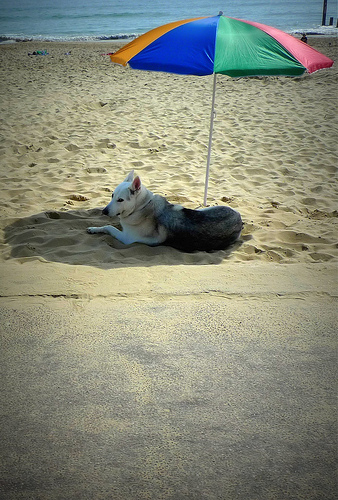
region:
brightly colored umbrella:
[103, 7, 333, 82]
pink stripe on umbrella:
[230, 13, 334, 67]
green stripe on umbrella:
[212, 12, 305, 75]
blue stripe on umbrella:
[124, 10, 217, 75]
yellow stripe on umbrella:
[102, 13, 210, 66]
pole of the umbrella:
[194, 71, 220, 208]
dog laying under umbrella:
[77, 162, 236, 250]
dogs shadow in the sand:
[2, 206, 219, 262]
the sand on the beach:
[0, 33, 334, 493]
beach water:
[0, 1, 337, 36]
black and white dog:
[84, 170, 248, 255]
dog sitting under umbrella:
[89, 165, 248, 258]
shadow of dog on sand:
[0, 201, 225, 268]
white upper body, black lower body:
[81, 169, 250, 251]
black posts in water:
[317, 0, 336, 31]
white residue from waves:
[0, 23, 337, 40]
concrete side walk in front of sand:
[2, 270, 335, 499]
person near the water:
[297, 32, 310, 46]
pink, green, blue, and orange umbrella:
[106, 10, 334, 80]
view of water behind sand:
[0, 0, 336, 35]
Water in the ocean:
[1, 1, 337, 36]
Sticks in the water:
[320, 1, 336, 27]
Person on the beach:
[300, 32, 307, 42]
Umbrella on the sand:
[110, 11, 333, 206]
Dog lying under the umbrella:
[85, 170, 242, 253]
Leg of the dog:
[86, 224, 123, 242]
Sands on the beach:
[3, 38, 334, 266]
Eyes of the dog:
[110, 191, 123, 203]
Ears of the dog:
[123, 167, 141, 192]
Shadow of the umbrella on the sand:
[2, 209, 234, 267]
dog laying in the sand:
[84, 165, 241, 252]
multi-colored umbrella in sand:
[106, 7, 329, 204]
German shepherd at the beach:
[79, 0, 331, 252]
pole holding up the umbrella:
[199, 72, 214, 202]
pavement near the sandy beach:
[0, 298, 332, 493]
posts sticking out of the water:
[317, 0, 330, 22]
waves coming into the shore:
[1, 26, 333, 37]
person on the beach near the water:
[297, 27, 305, 40]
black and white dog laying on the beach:
[83, 165, 239, 249]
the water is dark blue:
[2, 1, 334, 43]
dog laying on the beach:
[61, 152, 288, 275]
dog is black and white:
[85, 159, 273, 282]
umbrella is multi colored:
[107, 3, 314, 98]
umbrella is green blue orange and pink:
[98, 7, 336, 107]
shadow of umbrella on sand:
[8, 193, 205, 268]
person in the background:
[295, 28, 320, 53]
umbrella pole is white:
[204, 71, 220, 217]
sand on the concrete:
[31, 302, 335, 393]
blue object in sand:
[24, 45, 53, 63]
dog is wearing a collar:
[128, 181, 163, 215]